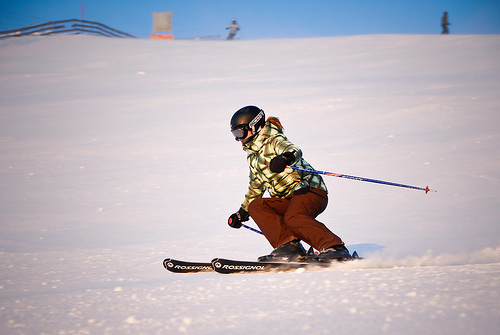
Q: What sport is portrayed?
A: Skiing.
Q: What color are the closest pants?
A: Red.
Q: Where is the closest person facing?
A: Left.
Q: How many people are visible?
A: 3.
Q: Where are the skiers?
A: In the snow.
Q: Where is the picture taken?
A: Ski slope.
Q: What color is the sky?
A: Blue.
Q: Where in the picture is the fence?
A: Top left.